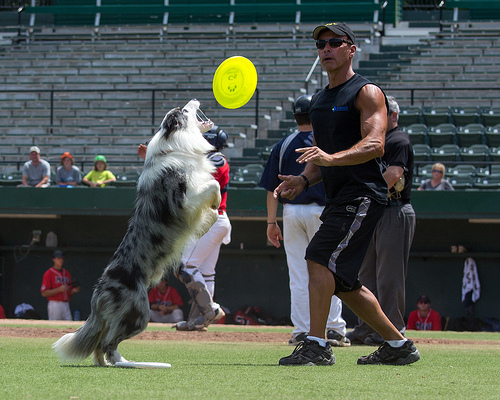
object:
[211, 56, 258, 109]
frisbee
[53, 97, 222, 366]
dog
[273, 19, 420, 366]
man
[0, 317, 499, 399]
grass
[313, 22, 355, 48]
hat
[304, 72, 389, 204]
shirt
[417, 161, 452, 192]
person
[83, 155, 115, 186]
person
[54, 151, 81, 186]
person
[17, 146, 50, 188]
person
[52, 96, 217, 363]
long coat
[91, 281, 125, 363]
hind legs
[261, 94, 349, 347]
person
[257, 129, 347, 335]
baseball uniform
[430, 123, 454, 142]
seat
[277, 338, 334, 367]
shoe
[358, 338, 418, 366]
shoe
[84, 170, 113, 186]
shirt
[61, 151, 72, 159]
hat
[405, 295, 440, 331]
person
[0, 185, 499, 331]
dugout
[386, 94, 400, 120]
hair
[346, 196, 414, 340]
slacks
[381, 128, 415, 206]
shirt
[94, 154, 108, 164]
hat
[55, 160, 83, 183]
shirt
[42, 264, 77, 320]
baseball outfit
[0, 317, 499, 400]
field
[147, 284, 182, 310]
shirt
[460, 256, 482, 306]
towel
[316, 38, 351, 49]
sunglasses